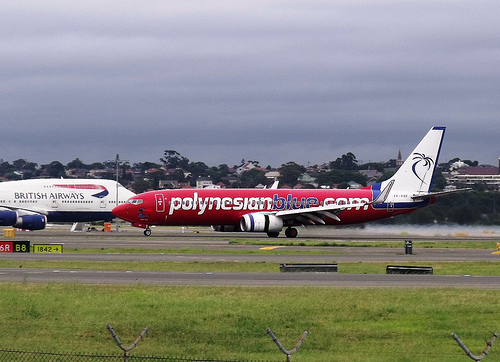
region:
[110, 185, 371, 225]
red body of airplane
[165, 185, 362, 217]
blue and white lettering on red plane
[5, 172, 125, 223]
white airplane next to red airplane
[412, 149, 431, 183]
tree logo painted on tail of red plane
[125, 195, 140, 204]
front windows of red airplane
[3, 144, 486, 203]
line of trees and houses behind airplanes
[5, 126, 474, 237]
two airplanes on tarmac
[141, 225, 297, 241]
wheels of red airplane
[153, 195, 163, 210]
door of red airplane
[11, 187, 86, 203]
black lettering on white airplane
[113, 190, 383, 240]
Large red colored plane parked on a gray landing strip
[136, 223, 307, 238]
Black tires and landing gear of a plane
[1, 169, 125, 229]
Large white and blue plane with many windows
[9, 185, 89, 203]
Blue writing that says British Airways on a white background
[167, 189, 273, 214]
White letters reading Polynesian on a red background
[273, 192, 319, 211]
The word Blue written in blue on a red background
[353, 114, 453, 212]
White tail of a plane with blue parts and logo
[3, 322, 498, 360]
Gray metal barbed wire fence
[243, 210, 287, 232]
White engine of a plane with blue and black colored rings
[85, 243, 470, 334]
Field of green grass on an airfield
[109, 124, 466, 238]
red colored plane parked on the runway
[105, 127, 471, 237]
red plane with "polynesian blue.com" on the side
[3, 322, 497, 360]
wire fence with wooden posts holding it up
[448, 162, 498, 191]
large building with many windows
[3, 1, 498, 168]
cloudy overcast sky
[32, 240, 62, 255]
yellow sign with an arrow pointing to the right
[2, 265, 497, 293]
gray colored paved runway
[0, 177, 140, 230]
white plane with blue writing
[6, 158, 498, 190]
buildings in the background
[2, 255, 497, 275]
grassy area between runways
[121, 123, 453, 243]
Red, white, and blue airplane.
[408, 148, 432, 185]
Palm tree on tail of the plane.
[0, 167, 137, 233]
White airplane on the ground.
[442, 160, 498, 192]
Building in the background.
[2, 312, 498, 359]
Fence in the forefront.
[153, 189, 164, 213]
Door on the airplane.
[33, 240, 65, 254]
Yellow sign on the ground.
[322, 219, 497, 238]
White smoke on the ground.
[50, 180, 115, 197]
Red and blue stripe on the plane.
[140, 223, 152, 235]
Front wheel on the plane.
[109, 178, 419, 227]
the plane body is red in color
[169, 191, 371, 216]
the plane has lettering on the side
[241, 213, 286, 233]
the engine is under the wing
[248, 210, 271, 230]
the engine has two stripes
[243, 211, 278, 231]
the stripes are black in color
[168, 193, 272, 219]
the writing is white in color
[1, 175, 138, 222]
the plane is painted white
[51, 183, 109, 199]
the plane has a logo on the body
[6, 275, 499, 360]
the grass is green in color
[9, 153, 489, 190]
trees are in the distance